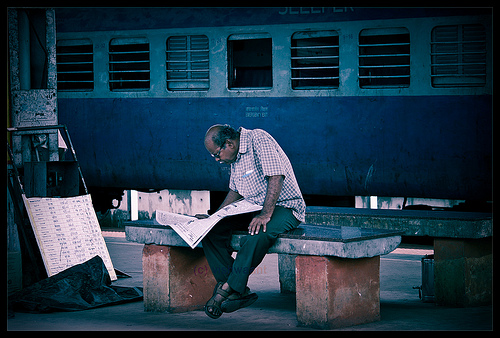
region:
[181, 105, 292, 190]
man wears glasses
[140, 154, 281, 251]
man reads a newspaper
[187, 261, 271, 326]
man wears sandals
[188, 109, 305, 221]
man wears checked shirt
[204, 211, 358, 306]
man sits on concrete bench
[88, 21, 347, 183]
old train car behind man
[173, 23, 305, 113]
one window broken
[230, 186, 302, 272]
man's hand on his knee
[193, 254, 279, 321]
man's feet are crossed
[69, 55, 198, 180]
train car is dirty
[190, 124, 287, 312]
The man is reading a newspaper.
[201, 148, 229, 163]
The man is wearing glasses.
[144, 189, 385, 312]
The man is sitting on the bench.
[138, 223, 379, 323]
The bench is made out of concrete.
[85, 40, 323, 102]
The train car has windows.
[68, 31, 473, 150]
The train car is old.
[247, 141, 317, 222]
The man has on a checkered shirt.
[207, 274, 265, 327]
The man has on brown sandals.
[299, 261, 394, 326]
The leg of the bench is red.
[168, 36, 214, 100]
The window on the train is closed.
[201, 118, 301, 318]
Older gentleman sitting on bench.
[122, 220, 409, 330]
Concrete bench with man.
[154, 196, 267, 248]
Newspaper being read by man.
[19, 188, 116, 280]
Stand with paper on it.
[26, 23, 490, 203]
Train in the background.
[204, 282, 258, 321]
Man wearing sandals.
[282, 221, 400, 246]
Reflections on the top of bench.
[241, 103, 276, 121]
Identifying mark on the train.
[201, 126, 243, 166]
Man wearing glasses.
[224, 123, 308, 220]
Man wearing a checkered shirt.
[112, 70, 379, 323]
a man sitting on a bench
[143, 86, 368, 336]
a man reading the paper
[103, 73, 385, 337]
a man sitting on a cement bench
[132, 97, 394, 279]
a man with glasses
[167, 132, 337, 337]
a man with his legs crossed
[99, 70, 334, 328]
a man reading paper on bench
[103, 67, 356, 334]
a man reading the paper during the day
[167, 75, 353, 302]
sitting and reading paper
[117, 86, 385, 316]
man on old bench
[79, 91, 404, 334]
man on old cement bench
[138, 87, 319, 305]
the man is reading a newspaper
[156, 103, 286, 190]
the man is wearing glasses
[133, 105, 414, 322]
the man is sitting down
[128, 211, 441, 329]
the bench is black and red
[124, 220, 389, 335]
the base of bench is made of brick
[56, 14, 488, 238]
the mode of transportation behind man is blue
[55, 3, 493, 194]
7 windows are on the mode of transportation pictured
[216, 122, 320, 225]
the man is wearing a checkered shirt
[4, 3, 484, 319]
a filter is applied to this picture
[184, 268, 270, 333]
the man is wearing sandals